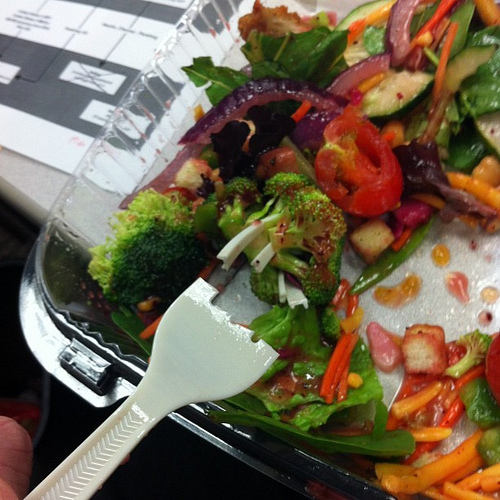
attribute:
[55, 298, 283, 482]
fork — plastic, broken, white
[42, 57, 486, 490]
container — plastic, clear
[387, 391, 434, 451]
cheese — cheddar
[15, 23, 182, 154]
paper — piece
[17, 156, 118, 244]
table — grey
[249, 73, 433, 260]
dressing — pink, raspberry